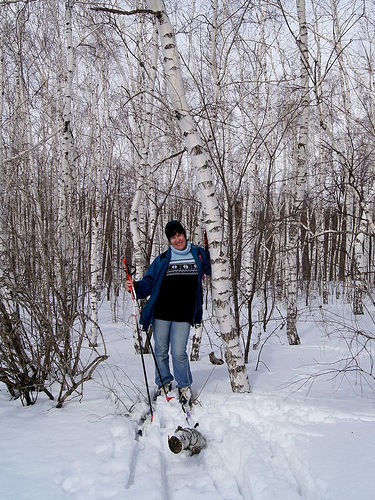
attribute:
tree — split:
[167, 423, 213, 464]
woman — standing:
[118, 215, 214, 405]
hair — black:
[164, 215, 185, 236]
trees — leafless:
[9, 9, 374, 309]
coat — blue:
[129, 244, 213, 328]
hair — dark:
[160, 217, 187, 240]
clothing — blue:
[134, 243, 213, 390]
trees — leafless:
[7, 7, 373, 371]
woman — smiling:
[133, 214, 218, 305]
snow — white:
[210, 391, 362, 493]